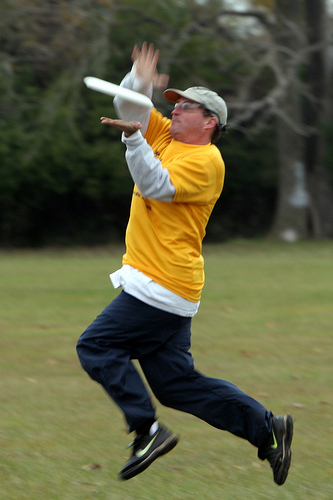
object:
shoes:
[115, 422, 179, 483]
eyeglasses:
[170, 100, 206, 113]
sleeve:
[113, 70, 157, 137]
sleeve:
[119, 135, 214, 201]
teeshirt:
[109, 65, 226, 317]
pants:
[67, 285, 268, 452]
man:
[73, 39, 303, 496]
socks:
[150, 420, 159, 435]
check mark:
[270, 428, 278, 450]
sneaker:
[265, 415, 292, 485]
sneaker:
[117, 423, 178, 481]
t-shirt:
[122, 117, 223, 304]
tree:
[215, 0, 331, 242]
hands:
[93, 111, 143, 133]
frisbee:
[73, 70, 193, 123]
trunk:
[270, 30, 323, 246]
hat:
[163, 85, 227, 125]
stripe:
[270, 430, 278, 449]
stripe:
[136, 430, 157, 457]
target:
[284, 153, 312, 212]